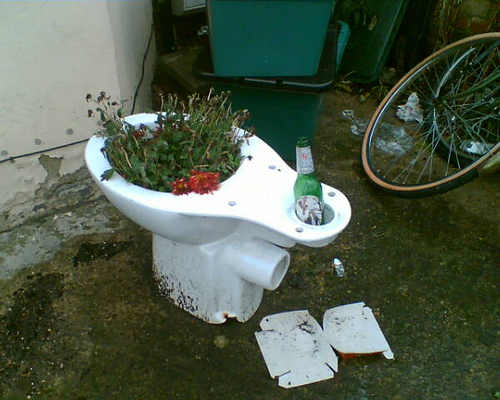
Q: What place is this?
A: It is a yard.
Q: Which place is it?
A: It is a yard.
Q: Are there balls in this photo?
A: No, there are no balls.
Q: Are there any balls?
A: No, there are no balls.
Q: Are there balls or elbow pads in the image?
A: No, there are no balls or elbow pads.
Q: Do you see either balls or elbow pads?
A: No, there are no balls or elbow pads.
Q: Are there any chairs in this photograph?
A: No, there are no chairs.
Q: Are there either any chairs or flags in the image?
A: No, there are no chairs or flags.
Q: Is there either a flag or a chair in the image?
A: No, there are no chairs or flags.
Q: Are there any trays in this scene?
A: No, there are no trays.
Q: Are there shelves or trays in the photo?
A: No, there are no trays or shelves.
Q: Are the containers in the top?
A: Yes, the containers are in the top of the image.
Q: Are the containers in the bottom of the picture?
A: No, the containers are in the top of the image.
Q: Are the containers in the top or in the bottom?
A: The containers are in the top of the image.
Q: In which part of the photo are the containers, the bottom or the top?
A: The containers are in the top of the image.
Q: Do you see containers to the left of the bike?
A: Yes, there are containers to the left of the bike.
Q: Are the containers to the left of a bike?
A: Yes, the containers are to the left of a bike.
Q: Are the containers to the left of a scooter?
A: No, the containers are to the left of a bike.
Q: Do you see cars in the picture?
A: No, there are no cars.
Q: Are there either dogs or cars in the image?
A: No, there are no cars or dogs.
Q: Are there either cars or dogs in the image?
A: No, there are no cars or dogs.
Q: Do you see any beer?
A: Yes, there is beer.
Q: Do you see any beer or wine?
A: Yes, there is beer.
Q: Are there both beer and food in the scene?
A: No, there is beer but no food.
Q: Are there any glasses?
A: No, there are no glasses.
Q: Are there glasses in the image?
A: No, there are no glasses.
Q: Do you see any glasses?
A: No, there are no glasses.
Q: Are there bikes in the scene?
A: Yes, there is a bike.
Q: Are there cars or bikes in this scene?
A: Yes, there is a bike.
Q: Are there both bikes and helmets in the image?
A: No, there is a bike but no helmets.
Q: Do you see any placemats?
A: No, there are no placemats.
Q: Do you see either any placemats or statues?
A: No, there are no placemats or statues.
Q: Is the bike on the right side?
A: Yes, the bike is on the right of the image.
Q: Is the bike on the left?
A: No, the bike is on the right of the image.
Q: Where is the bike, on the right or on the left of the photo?
A: The bike is on the right of the image.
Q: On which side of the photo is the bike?
A: The bike is on the right of the image.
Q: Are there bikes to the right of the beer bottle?
A: Yes, there is a bike to the right of the beer bottle.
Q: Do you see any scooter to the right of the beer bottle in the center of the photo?
A: No, there is a bike to the right of the beer bottle.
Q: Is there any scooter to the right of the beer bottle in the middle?
A: No, there is a bike to the right of the beer bottle.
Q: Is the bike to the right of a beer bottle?
A: Yes, the bike is to the right of a beer bottle.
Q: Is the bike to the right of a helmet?
A: No, the bike is to the right of a beer bottle.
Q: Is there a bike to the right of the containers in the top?
A: Yes, there is a bike to the right of the containers.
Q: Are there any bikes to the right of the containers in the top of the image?
A: Yes, there is a bike to the right of the containers.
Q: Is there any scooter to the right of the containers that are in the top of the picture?
A: No, there is a bike to the right of the containers.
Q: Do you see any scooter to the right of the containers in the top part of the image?
A: No, there is a bike to the right of the containers.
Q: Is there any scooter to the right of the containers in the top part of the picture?
A: No, there is a bike to the right of the containers.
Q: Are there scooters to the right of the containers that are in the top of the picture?
A: No, there is a bike to the right of the containers.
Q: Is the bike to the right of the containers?
A: Yes, the bike is to the right of the containers.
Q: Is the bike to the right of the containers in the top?
A: Yes, the bike is to the right of the containers.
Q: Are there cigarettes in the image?
A: No, there are no cigarettes.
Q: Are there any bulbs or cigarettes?
A: No, there are no cigarettes or bulbs.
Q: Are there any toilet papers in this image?
A: No, there are no toilet papers.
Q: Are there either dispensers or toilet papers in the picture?
A: No, there are no toilet papers or dispensers.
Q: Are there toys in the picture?
A: No, there are no toys.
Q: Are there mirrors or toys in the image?
A: No, there are no toys or mirrors.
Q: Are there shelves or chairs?
A: No, there are no chairs or shelves.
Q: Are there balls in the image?
A: No, there are no balls.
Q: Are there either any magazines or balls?
A: No, there are no balls or magazines.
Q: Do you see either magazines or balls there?
A: No, there are no balls or magazines.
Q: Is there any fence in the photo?
A: No, there are no fences.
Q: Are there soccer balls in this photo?
A: No, there are no soccer balls.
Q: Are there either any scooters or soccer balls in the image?
A: No, there are no soccer balls or scooters.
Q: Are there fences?
A: No, there are no fences.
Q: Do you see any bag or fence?
A: No, there are no fences or bags.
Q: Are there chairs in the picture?
A: No, there are no chairs.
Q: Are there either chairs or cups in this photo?
A: No, there are no chairs or cups.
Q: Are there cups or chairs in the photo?
A: No, there are no chairs or cups.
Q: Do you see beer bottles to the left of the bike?
A: Yes, there is a beer bottle to the left of the bike.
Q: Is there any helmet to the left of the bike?
A: No, there is a beer bottle to the left of the bike.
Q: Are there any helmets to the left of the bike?
A: No, there is a beer bottle to the left of the bike.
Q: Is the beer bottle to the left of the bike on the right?
A: Yes, the beer bottle is to the left of the bike.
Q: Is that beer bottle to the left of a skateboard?
A: No, the beer bottle is to the left of the bike.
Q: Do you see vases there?
A: No, there are no vases.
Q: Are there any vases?
A: No, there are no vases.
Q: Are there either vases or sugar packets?
A: No, there are no vases or sugar packets.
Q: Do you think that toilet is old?
A: Yes, the toilet is old.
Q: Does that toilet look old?
A: Yes, the toilet is old.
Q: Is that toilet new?
A: No, the toilet is old.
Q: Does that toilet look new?
A: No, the toilet is old.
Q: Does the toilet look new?
A: No, the toilet is old.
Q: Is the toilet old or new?
A: The toilet is old.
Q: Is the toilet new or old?
A: The toilet is old.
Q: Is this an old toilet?
A: Yes, this is an old toilet.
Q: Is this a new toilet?
A: No, this is an old toilet.